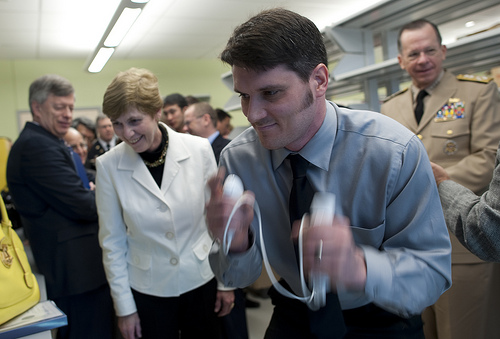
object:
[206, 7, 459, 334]
man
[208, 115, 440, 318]
shirt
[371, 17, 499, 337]
man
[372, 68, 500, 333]
uniform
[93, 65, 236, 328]
woman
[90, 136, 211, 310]
jacket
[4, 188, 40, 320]
purse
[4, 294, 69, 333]
table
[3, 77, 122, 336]
man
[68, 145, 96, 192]
folder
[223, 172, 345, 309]
controllers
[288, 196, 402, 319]
arms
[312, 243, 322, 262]
ring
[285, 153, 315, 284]
tie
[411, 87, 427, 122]
tie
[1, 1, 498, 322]
background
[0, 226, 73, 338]
stand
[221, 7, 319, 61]
hair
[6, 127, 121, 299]
blazer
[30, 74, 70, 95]
hair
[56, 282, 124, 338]
pants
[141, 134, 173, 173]
necklace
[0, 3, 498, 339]
people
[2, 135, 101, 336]
suit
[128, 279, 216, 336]
skirt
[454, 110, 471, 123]
pin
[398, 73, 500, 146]
jacket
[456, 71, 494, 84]
pin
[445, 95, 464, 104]
pin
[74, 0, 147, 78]
lights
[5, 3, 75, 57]
wall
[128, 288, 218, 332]
pants